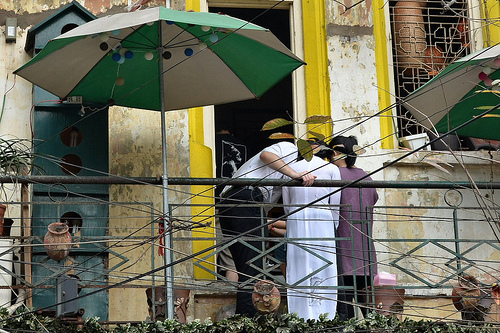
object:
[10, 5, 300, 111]
umbrella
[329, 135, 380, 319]
people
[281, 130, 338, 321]
person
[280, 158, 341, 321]
dress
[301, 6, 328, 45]
paint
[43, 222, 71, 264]
pot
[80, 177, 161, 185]
railing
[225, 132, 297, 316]
man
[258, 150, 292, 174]
arm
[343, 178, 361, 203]
purple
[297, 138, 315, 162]
leaves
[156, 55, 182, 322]
pole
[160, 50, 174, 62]
balls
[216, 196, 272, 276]
slacks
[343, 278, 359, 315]
leggings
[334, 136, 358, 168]
hair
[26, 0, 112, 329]
bird house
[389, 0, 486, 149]
window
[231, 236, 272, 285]
shorts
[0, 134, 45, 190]
plants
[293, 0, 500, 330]
building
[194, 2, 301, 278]
door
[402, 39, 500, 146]
umbrellas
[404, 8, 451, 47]
grill